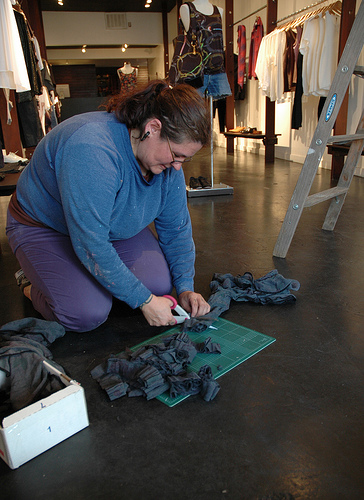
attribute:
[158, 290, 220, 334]
scissors — pink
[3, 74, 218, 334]
lady — blue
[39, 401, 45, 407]
seven — blue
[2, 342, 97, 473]
box — white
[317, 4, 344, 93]
shirt — white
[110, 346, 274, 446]
fabric — cut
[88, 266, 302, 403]
material — blue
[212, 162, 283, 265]
floor — gray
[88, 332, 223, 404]
material — gray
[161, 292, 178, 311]
handle — pink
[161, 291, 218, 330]
scissors — pink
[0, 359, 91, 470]
box — white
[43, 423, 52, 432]
number — blue